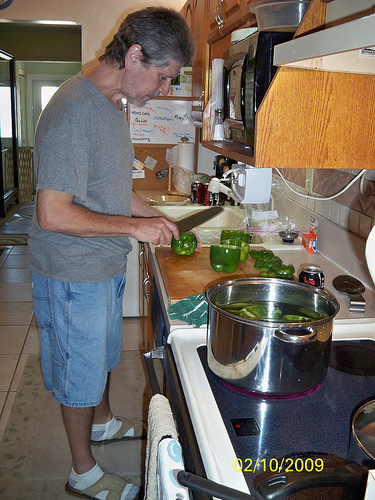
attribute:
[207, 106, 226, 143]
salt shaker — clear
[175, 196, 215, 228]
knife — silver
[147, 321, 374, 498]
stove — blue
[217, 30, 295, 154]
microwave — black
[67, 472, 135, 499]
sandal — tan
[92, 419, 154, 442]
sandal — tan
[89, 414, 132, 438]
sock — white, gray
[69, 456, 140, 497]
sock — white, gray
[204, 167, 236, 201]
faucet — white, kitchen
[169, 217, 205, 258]
pepper — green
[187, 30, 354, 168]
shelf — wooden